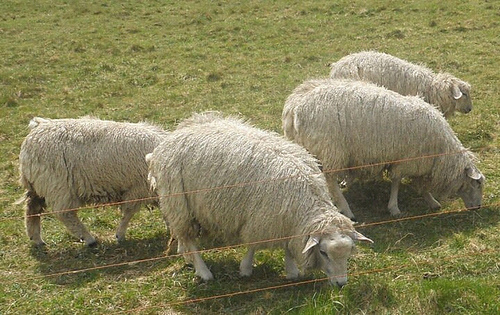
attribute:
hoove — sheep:
[84, 237, 101, 249]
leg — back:
[47, 196, 99, 247]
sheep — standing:
[321, 40, 491, 154]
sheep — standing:
[281, 72, 486, 213]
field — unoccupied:
[358, 10, 437, 45]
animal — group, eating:
[20, 113, 168, 254]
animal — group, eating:
[149, 111, 373, 286]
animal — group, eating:
[280, 77, 484, 219]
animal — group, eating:
[327, 48, 472, 120]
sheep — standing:
[136, 102, 382, 297]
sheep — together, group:
[18, 46, 489, 285]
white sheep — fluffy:
[9, 50, 484, 286]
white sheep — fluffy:
[14, 112, 171, 247]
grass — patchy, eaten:
[103, 38, 295, 120]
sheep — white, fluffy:
[8, 109, 177, 252]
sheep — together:
[145, 114, 368, 300]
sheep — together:
[281, 70, 492, 228]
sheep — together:
[18, 111, 166, 264]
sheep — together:
[327, 52, 475, 120]